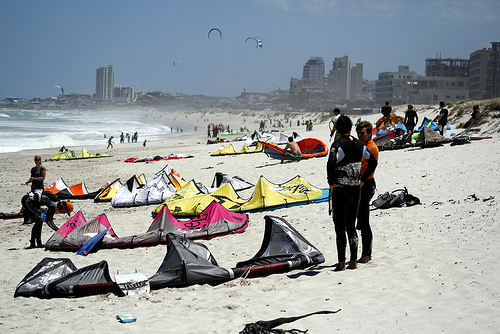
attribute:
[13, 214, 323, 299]
kite — grey, red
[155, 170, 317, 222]
kite — yellow, white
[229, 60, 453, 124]
buildings — tall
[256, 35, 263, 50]
white kite — small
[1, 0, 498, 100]
blue sky — overcast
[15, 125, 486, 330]
beach — sandy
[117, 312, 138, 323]
object — square, blue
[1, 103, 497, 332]
beach — light tan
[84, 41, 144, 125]
building — tall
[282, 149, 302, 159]
shorts — green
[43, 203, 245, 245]
kite — pink, grey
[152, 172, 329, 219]
tarp — yellow, black